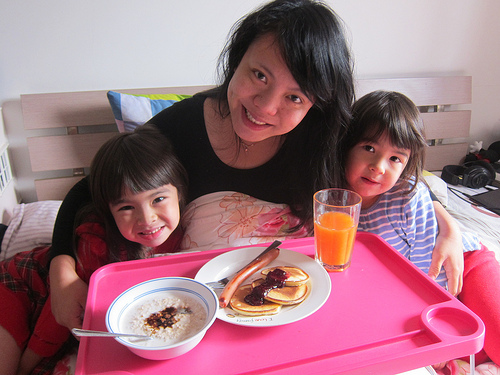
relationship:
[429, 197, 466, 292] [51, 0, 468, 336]
hand of woman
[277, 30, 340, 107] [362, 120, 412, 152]
bang on forehead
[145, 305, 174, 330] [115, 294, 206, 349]
topping on oatmeal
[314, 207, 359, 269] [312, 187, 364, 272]
orange juice in glass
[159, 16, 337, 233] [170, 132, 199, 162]
woman wearing shirt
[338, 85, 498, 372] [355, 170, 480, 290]
girl wearing striped shirt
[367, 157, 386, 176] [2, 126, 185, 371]
nose of girl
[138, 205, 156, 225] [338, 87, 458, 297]
nose of girl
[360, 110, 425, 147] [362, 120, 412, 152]
bangs on forehead